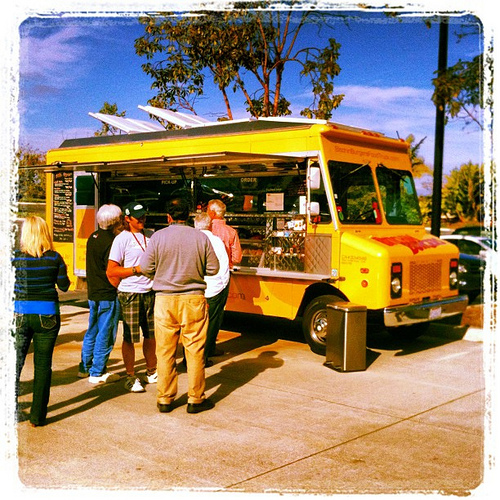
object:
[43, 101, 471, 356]
truck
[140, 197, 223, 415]
man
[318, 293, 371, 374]
trash can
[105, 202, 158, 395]
man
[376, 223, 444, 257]
letters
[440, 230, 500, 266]
cars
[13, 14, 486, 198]
sky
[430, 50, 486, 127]
tree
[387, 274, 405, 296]
headlight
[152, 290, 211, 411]
pants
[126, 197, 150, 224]
hat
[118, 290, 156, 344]
shorts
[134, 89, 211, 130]
vent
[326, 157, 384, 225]
windshield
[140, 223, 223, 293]
shirt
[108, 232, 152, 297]
shirt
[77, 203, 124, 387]
man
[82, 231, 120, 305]
shirt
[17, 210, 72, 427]
woman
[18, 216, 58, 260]
hair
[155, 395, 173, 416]
shoes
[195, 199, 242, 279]
man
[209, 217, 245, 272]
shirt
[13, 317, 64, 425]
jeans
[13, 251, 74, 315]
sweater